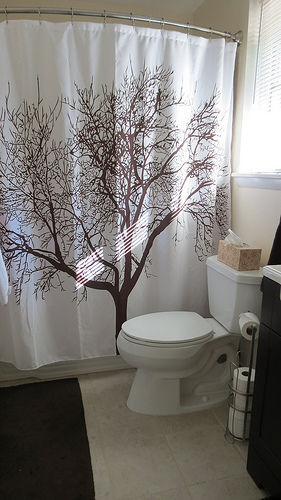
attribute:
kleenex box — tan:
[216, 230, 263, 273]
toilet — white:
[115, 256, 265, 417]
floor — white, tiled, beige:
[2, 367, 260, 500]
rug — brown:
[0, 376, 97, 499]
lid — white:
[120, 310, 213, 344]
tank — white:
[206, 254, 266, 334]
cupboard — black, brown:
[246, 277, 280, 500]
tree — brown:
[3, 56, 232, 356]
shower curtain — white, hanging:
[1, 19, 241, 373]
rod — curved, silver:
[1, 3, 244, 43]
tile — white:
[107, 448, 187, 499]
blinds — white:
[253, 0, 281, 168]